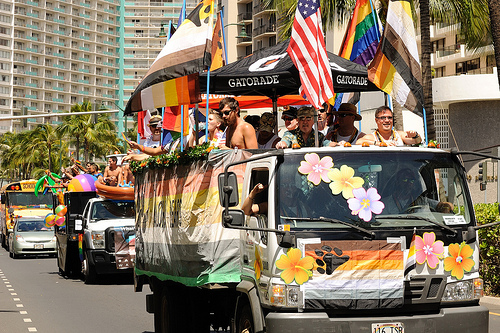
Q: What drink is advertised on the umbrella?
A: Gatorade.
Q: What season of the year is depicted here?
A: Summer.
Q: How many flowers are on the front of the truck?
A: 6.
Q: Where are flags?
A: On the truck.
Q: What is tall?
A: Buildings.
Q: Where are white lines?
A: On the street.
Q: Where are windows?
A: On trucks.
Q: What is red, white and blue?
A: American flag.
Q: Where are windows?
A: On buildings.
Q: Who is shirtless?
A: One man.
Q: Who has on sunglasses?
A: One man in truck.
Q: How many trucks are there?
A: Two.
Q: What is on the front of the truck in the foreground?
A: Flowers.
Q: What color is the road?
A: Gray.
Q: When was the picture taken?
A: Daytime.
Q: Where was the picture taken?
A: A city street.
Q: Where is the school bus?
A: Behind the car.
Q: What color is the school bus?
A: Yellow.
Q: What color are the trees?
A: Green.